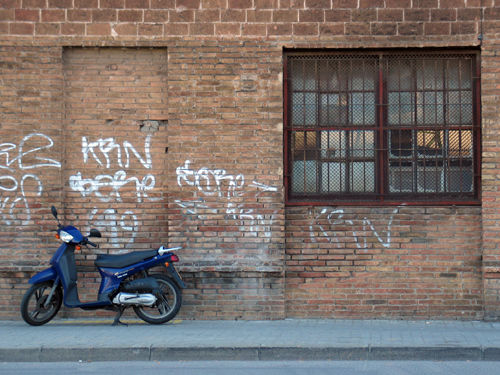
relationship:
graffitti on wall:
[1, 131, 406, 258] [194, 106, 251, 251]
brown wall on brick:
[0, 0, 499, 321] [449, 20, 478, 37]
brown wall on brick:
[0, 0, 499, 321] [396, 21, 425, 32]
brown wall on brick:
[0, 0, 499, 321] [344, 18, 369, 38]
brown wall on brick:
[0, 0, 499, 321] [270, 23, 292, 36]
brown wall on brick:
[0, 0, 499, 321] [167, 22, 190, 33]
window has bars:
[287, 54, 478, 200] [283, 49, 480, 206]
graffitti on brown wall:
[1, 131, 406, 258] [0, 0, 499, 321]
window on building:
[287, 54, 478, 200] [2, 1, 498, 321]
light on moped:
[59, 229, 74, 244] [58, 221, 84, 244]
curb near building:
[4, 319, 499, 364] [2, 1, 498, 321]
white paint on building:
[177, 201, 274, 303] [2, 1, 498, 321]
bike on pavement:
[20, 205, 187, 327] [0, 318, 496, 373]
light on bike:
[56, 225, 76, 244] [19, 208, 187, 339]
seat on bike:
[93, 252, 158, 270] [21, 195, 184, 332]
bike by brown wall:
[20, 205, 187, 327] [0, 0, 499, 321]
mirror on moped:
[49, 204, 58, 216] [20, 205, 186, 326]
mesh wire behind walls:
[286, 48, 480, 208] [283, 210, 487, 327]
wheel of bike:
[124, 263, 194, 317] [26, 201, 168, 321]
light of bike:
[59, 229, 74, 244] [21, 195, 184, 332]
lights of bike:
[172, 254, 180, 261] [20, 205, 187, 327]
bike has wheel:
[14, 209, 197, 330] [19, 277, 65, 326]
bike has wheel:
[14, 209, 197, 330] [124, 273, 186, 326]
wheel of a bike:
[132, 274, 183, 324] [21, 195, 184, 332]